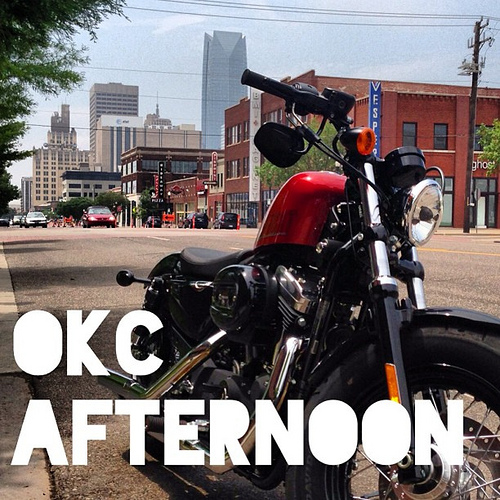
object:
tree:
[261, 119, 348, 189]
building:
[200, 27, 252, 162]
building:
[224, 71, 497, 231]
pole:
[461, 19, 482, 233]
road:
[0, 217, 498, 498]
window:
[433, 122, 448, 149]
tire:
[289, 306, 497, 499]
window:
[474, 126, 484, 148]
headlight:
[401, 179, 444, 247]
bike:
[113, 69, 499, 499]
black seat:
[178, 246, 256, 281]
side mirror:
[253, 121, 309, 169]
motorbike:
[96, 70, 500, 499]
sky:
[1, 0, 498, 202]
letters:
[10, 308, 465, 467]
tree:
[469, 116, 498, 234]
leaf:
[478, 125, 488, 133]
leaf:
[478, 139, 488, 149]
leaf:
[491, 130, 499, 139]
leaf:
[478, 153, 485, 160]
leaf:
[491, 156, 498, 165]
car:
[81, 205, 115, 228]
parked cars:
[144, 213, 238, 230]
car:
[24, 211, 47, 228]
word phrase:
[13, 306, 465, 469]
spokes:
[345, 391, 499, 500]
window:
[171, 160, 196, 175]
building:
[119, 146, 221, 225]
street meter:
[178, 212, 240, 229]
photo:
[0, 0, 500, 499]